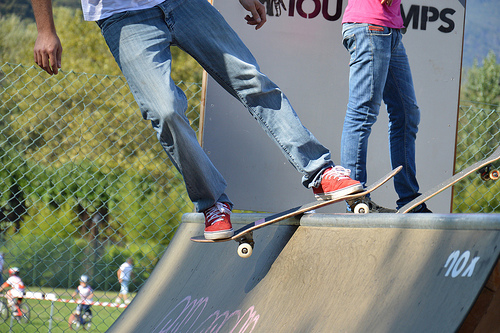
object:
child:
[70, 274, 96, 330]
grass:
[0, 286, 137, 332]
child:
[0, 267, 30, 322]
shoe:
[204, 201, 235, 240]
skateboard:
[190, 165, 403, 258]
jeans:
[95, 0, 335, 212]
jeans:
[342, 22, 422, 212]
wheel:
[238, 243, 252, 258]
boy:
[30, 0, 364, 241]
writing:
[152, 295, 259, 333]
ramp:
[105, 213, 500, 333]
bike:
[68, 302, 92, 331]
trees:
[0, 0, 499, 290]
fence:
[0, 64, 206, 332]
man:
[116, 258, 133, 307]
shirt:
[341, 0, 406, 29]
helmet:
[9, 266, 20, 276]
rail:
[180, 212, 499, 231]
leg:
[101, 20, 231, 212]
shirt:
[119, 262, 133, 281]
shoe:
[312, 164, 363, 200]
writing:
[442, 250, 481, 280]